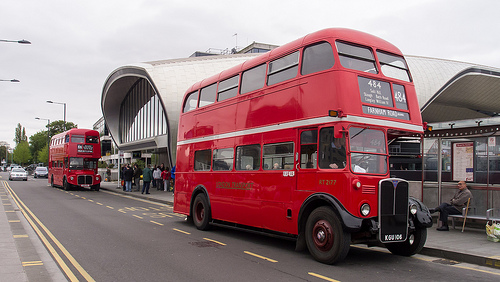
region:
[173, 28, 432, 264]
Red Double decker bus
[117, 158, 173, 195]
People waiting to go inside building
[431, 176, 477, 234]
Man sitting in a chair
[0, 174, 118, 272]
Street for cars to drive on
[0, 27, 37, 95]
Light poles overhanging the street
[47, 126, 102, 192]
Red Double decker bus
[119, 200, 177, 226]
Yellow lettering on the street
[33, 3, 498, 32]
Cloudy skys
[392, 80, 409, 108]
Bus number 484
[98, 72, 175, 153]
Building that people are going in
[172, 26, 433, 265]
Red double decker bus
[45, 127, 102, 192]
Red double decker bus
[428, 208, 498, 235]
Bench on side of road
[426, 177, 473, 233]
Man sitting on a bench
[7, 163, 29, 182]
Car driving on road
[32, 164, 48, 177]
Car driving on road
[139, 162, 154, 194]
Man in green jacket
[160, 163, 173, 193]
Man in red jacket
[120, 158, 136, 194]
Man in black jacket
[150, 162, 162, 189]
Person in white jacket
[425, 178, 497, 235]
a person is sitting on the bench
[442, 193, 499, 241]
a bag is on the platform in front of the bench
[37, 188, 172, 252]
yellow markings on the road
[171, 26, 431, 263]
a red color double-decker bus is on the road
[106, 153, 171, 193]
people are waiting in the platform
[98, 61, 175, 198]
people are standing under the shade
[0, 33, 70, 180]
street lamps on both sides of the road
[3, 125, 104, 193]
traffic is available on the road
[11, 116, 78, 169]
well grown trees with green leaves in its branches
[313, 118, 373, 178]
the driver is sitting in front of the steering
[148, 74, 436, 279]
red double decker boat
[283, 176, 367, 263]
black tires on bus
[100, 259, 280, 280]
road is dark grey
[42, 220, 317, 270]
yellow line on road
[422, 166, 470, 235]
man sits on bench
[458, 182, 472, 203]
man has grey shirt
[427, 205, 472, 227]
man has black pants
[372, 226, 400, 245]
black and white license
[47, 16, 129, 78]
grey and white sky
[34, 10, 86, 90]
thick clouds in sky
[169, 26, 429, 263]
Red bus parked by curb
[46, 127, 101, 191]
Red bus parked by curb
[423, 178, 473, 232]
Older man sitting on bench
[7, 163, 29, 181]
Silver car on road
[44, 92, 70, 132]
Street lamp in background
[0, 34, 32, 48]
Street lamp above road